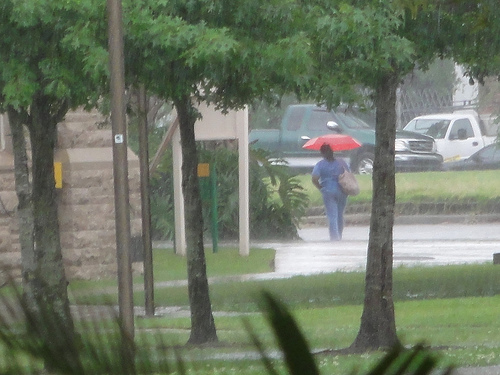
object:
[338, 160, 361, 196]
purse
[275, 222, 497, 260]
asphalt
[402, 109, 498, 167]
truck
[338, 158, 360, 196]
bag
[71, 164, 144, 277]
blocks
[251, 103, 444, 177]
truck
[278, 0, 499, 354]
trees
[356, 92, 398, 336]
tree trunk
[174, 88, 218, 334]
tree trunk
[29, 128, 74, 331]
tree trunk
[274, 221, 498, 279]
road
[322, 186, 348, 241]
jeans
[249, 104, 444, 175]
green truck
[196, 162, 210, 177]
sign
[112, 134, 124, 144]
sign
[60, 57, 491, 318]
stormy day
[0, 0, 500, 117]
leaves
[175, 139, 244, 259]
wooden sign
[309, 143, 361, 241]
woman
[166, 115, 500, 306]
park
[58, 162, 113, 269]
wall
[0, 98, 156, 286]
building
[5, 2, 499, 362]
day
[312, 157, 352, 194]
shirt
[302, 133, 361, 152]
red umbrella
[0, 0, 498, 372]
outdoors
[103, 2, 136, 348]
pole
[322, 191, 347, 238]
pants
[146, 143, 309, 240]
palm trees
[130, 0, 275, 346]
trees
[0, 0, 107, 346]
trees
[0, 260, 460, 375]
grass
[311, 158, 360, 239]
outfit